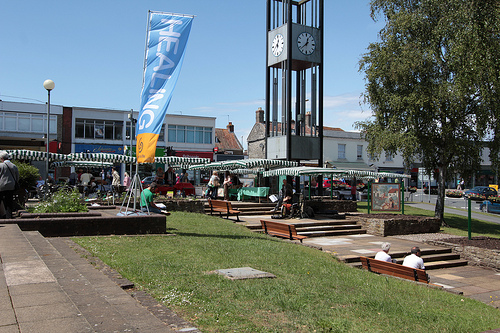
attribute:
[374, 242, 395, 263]
female — elderly, wooden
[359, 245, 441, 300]
bench — wood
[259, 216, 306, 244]
bench — wooden, brown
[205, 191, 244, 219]
bench — brown, wooden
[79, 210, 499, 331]
area — grassy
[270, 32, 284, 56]
clock — round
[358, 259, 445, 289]
bench — wood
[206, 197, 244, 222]
bench — wooden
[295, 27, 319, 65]
clock — metal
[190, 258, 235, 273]
grass — green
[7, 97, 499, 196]
buildings — lined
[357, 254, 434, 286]
bench — brown, wooden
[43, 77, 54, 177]
light post — metal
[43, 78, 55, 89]
globe — white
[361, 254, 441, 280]
bench — wooden